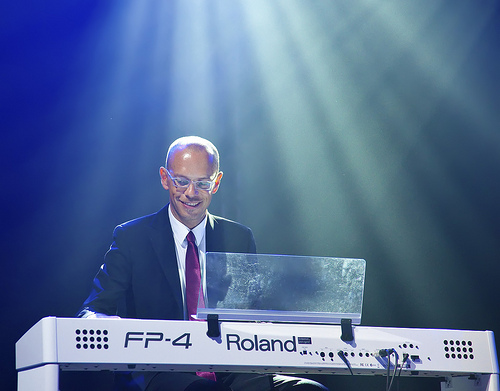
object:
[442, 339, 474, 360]
dots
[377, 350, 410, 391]
wires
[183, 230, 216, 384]
tie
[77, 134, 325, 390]
man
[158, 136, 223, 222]
head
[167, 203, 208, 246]
collar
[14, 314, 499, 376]
keyboard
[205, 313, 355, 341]
edge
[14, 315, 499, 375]
board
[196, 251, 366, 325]
board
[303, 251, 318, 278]
part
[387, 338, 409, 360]
part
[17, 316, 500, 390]
piano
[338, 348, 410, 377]
cords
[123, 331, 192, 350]
letters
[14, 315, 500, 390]
organ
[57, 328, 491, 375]
front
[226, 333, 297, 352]
word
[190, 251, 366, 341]
holder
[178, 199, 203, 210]
smile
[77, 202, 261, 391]
suit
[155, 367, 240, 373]
cords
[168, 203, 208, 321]
shirt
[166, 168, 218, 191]
eyeglasses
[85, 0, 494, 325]
lights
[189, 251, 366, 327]
screen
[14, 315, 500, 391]
table